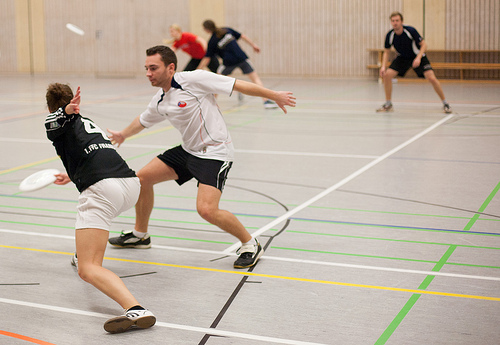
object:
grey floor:
[0, 79, 499, 345]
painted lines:
[0, 329, 57, 345]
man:
[103, 45, 297, 270]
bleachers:
[366, 47, 499, 83]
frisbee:
[17, 169, 61, 193]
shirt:
[42, 104, 137, 192]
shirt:
[136, 69, 236, 163]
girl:
[44, 83, 156, 333]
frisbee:
[64, 23, 85, 37]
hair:
[143, 44, 177, 73]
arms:
[201, 70, 275, 100]